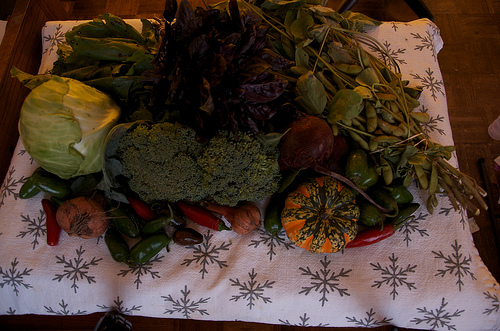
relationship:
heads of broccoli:
[120, 135, 242, 208] [114, 119, 286, 213]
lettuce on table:
[145, 4, 292, 119] [2, 13, 481, 329]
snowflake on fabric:
[224, 261, 277, 309] [1, 13, 484, 326]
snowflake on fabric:
[14, 202, 50, 248] [1, 13, 484, 326]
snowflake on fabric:
[408, 298, 466, 329] [1, 13, 484, 326]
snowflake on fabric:
[431, 239, 476, 289] [1, 13, 484, 326]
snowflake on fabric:
[178, 228, 235, 278] [1, 13, 484, 326]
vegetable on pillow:
[21, 71, 111, 199] [4, 13, 485, 324]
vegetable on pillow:
[108, 102, 265, 208] [4, 13, 485, 324]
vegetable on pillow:
[279, 179, 356, 253] [4, 13, 485, 324]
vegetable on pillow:
[275, 107, 333, 167] [4, 13, 485, 324]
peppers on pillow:
[125, 193, 157, 221] [4, 13, 485, 324]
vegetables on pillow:
[52, 196, 112, 240] [4, 13, 485, 324]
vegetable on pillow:
[279, 178, 363, 256] [4, 13, 485, 324]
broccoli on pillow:
[117, 121, 210, 206] [4, 13, 485, 324]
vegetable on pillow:
[8, 64, 124, 182] [4, 13, 485, 324]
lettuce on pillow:
[139, 0, 296, 141] [4, 13, 485, 324]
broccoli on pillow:
[116, 120, 206, 208] [4, 13, 485, 324]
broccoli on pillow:
[194, 124, 279, 202] [4, 13, 485, 324]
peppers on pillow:
[35, 199, 62, 246] [4, 13, 485, 324]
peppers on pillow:
[176, 200, 229, 231] [4, 13, 485, 324]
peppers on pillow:
[340, 220, 395, 245] [4, 13, 485, 324]